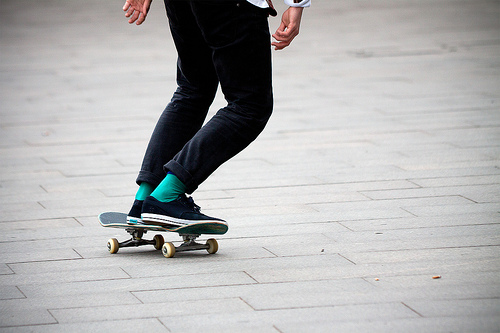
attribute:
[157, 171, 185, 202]
sock — green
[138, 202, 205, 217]
sneaker — black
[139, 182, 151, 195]
sock — green